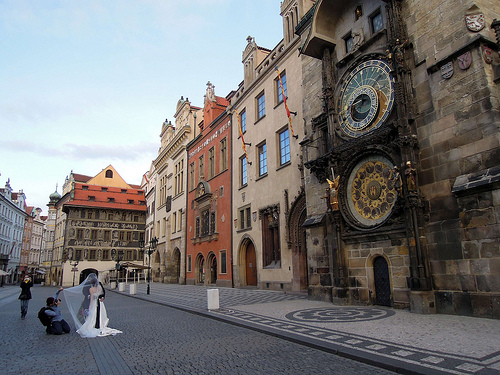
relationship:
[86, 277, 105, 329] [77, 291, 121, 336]
bride has a dress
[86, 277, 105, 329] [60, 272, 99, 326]
bride has a veil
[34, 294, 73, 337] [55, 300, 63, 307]
photographer getting a picture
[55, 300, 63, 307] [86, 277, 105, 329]
picture of bride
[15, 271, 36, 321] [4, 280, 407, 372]
people on street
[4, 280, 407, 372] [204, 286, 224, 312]
street has a rectangle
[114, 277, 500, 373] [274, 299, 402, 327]
sidewalk has a design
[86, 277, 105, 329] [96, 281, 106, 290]
woman has a shoulder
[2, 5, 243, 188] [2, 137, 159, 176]
sky has a cloud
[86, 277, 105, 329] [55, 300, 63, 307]
bride getting a picture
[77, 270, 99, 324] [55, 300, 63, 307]
groom getting a picture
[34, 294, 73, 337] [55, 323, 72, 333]
photographer on knees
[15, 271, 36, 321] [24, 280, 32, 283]
people taking a picture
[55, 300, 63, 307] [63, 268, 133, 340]
picture of couple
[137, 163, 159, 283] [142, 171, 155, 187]
building has a flag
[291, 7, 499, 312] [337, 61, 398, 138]
building has a clock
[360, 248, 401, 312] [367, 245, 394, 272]
entry has a arch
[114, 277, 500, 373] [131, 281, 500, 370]
sidewalk has a pattern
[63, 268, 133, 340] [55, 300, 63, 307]
couple getting picture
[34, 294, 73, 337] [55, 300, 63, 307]
photographer taking picture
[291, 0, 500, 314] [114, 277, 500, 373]
building are in front of sidewalk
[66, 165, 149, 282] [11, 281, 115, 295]
building at end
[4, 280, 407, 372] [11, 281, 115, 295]
street has an end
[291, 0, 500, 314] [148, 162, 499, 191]
building are in a line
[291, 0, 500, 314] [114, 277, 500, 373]
building in front of sidewalk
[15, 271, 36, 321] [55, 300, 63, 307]
people taking a picture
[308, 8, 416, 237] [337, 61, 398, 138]
tower has a clock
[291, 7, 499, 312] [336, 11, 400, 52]
building has windows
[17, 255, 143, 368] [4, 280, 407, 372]
people are on street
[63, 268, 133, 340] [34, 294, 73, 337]
couple with photographer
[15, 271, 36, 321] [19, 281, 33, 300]
people has a coat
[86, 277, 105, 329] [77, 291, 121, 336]
bride in dress